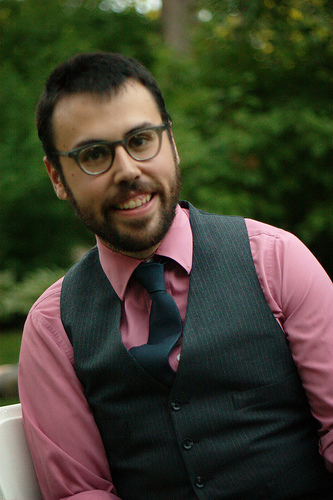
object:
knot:
[133, 263, 167, 293]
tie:
[126, 264, 182, 387]